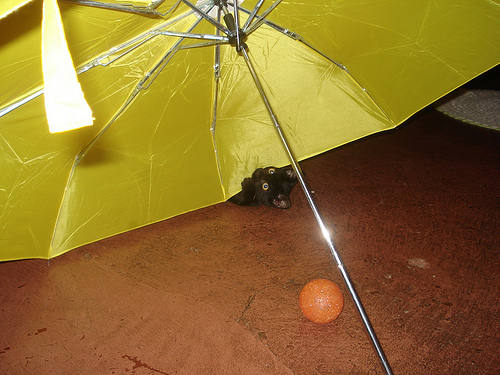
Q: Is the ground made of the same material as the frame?
A: No, the ground is made of cement and the frame is made of metal.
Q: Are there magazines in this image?
A: No, there are no magazines.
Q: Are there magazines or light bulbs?
A: No, there are no magazines or light bulbs.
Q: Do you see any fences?
A: No, there are no fences.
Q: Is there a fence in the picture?
A: No, there are no fences.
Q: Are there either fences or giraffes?
A: No, there are no fences or giraffes.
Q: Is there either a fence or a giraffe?
A: No, there are no fences or giraffes.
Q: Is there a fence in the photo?
A: No, there are no fences.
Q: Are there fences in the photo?
A: No, there are no fences.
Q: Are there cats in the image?
A: Yes, there is a cat.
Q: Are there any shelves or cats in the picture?
A: Yes, there is a cat.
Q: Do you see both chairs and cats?
A: No, there is a cat but no chairs.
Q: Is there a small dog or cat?
A: Yes, there is a small cat.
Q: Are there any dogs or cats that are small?
A: Yes, the cat is small.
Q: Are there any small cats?
A: Yes, there is a small cat.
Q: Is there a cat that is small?
A: Yes, there is a cat that is small.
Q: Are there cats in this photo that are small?
A: Yes, there is a cat that is small.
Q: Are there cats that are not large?
A: Yes, there is a small cat.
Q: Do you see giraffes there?
A: No, there are no giraffes.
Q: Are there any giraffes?
A: No, there are no giraffes.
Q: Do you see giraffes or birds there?
A: No, there are no giraffes or birds.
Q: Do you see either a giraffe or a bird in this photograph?
A: No, there are no giraffes or birds.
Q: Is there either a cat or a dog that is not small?
A: No, there is a cat but it is small.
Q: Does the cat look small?
A: Yes, the cat is small.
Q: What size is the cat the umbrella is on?
A: The cat is small.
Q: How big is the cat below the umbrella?
A: The cat is small.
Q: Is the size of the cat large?
A: No, the cat is small.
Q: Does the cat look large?
A: No, the cat is small.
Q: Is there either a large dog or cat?
A: No, there is a cat but it is small.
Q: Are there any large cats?
A: No, there is a cat but it is small.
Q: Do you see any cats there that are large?
A: No, there is a cat but it is small.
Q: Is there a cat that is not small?
A: No, there is a cat but it is small.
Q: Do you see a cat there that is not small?
A: No, there is a cat but it is small.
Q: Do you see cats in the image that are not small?
A: No, there is a cat but it is small.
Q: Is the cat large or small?
A: The cat is small.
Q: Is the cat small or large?
A: The cat is small.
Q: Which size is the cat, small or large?
A: The cat is small.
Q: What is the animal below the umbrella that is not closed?
A: The animal is a cat.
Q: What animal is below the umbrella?
A: The animal is a cat.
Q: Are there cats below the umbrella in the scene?
A: Yes, there is a cat below the umbrella.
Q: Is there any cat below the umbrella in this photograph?
A: Yes, there is a cat below the umbrella.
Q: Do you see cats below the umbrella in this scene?
A: Yes, there is a cat below the umbrella.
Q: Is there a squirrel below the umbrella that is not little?
A: No, there is a cat below the umbrella.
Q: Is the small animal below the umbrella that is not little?
A: Yes, the cat is below the umbrella.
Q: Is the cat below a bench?
A: No, the cat is below the umbrella.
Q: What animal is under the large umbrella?
A: The cat is under the umbrella.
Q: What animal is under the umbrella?
A: The cat is under the umbrella.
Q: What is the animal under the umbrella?
A: The animal is a cat.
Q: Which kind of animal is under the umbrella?
A: The animal is a cat.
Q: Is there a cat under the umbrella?
A: Yes, there is a cat under the umbrella.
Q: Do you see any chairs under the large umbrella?
A: No, there is a cat under the umbrella.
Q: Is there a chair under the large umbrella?
A: No, there is a cat under the umbrella.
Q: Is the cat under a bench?
A: No, the cat is under the umbrella.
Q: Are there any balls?
A: Yes, there is a ball.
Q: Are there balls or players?
A: Yes, there is a ball.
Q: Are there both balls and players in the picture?
A: No, there is a ball but no players.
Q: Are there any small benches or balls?
A: Yes, there is a small ball.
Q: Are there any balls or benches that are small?
A: Yes, the ball is small.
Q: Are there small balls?
A: Yes, there is a small ball.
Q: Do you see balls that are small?
A: Yes, there is a ball that is small.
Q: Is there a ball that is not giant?
A: Yes, there is a small ball.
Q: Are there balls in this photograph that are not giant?
A: Yes, there is a small ball.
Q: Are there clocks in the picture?
A: No, there are no clocks.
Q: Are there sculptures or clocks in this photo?
A: No, there are no clocks or sculptures.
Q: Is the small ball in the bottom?
A: Yes, the ball is in the bottom of the image.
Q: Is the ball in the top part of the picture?
A: No, the ball is in the bottom of the image.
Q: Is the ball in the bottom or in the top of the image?
A: The ball is in the bottom of the image.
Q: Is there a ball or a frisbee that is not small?
A: No, there is a ball but it is small.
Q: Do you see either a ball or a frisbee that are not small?
A: No, there is a ball but it is small.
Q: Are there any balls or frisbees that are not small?
A: No, there is a ball but it is small.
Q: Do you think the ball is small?
A: Yes, the ball is small.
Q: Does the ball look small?
A: Yes, the ball is small.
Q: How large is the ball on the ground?
A: The ball is small.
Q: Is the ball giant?
A: No, the ball is small.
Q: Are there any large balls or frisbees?
A: No, there is a ball but it is small.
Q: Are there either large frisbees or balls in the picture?
A: No, there is a ball but it is small.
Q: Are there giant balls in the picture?
A: No, there is a ball but it is small.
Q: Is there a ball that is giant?
A: No, there is a ball but it is small.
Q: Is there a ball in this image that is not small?
A: No, there is a ball but it is small.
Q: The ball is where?
A: The ball is on the ground.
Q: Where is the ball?
A: The ball is on the ground.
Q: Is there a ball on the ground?
A: Yes, there is a ball on the ground.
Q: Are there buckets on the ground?
A: No, there is a ball on the ground.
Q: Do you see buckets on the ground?
A: No, there is a ball on the ground.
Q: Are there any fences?
A: No, there are no fences.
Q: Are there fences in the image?
A: No, there are no fences.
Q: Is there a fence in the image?
A: No, there are no fences.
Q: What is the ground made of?
A: The ground is made of concrete.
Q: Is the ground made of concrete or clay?
A: The ground is made of concrete.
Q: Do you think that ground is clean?
A: Yes, the ground is clean.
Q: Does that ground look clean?
A: Yes, the ground is clean.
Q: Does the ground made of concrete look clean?
A: Yes, the ground is clean.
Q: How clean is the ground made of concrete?
A: The ground is clean.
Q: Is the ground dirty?
A: No, the ground is clean.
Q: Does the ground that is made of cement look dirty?
A: No, the ground is clean.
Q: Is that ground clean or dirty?
A: The ground is clean.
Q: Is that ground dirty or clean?
A: The ground is clean.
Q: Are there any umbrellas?
A: Yes, there is an umbrella.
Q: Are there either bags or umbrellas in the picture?
A: Yes, there is an umbrella.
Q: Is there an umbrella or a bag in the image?
A: Yes, there is an umbrella.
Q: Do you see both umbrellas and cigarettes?
A: No, there is an umbrella but no cigarettes.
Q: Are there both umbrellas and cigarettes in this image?
A: No, there is an umbrella but no cigarettes.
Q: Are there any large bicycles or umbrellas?
A: Yes, there is a large umbrella.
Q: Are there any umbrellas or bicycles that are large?
A: Yes, the umbrella is large.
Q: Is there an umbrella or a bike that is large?
A: Yes, the umbrella is large.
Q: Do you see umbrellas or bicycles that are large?
A: Yes, the umbrella is large.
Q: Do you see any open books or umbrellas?
A: Yes, there is an open umbrella.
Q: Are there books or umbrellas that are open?
A: Yes, the umbrella is open.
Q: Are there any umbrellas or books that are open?
A: Yes, the umbrella is open.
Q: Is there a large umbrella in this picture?
A: Yes, there is a large umbrella.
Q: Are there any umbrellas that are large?
A: Yes, there is an umbrella that is large.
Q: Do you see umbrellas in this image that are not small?
A: Yes, there is a large umbrella.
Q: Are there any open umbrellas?
A: Yes, there is an open umbrella.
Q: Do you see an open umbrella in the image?
A: Yes, there is an open umbrella.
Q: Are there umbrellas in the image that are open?
A: Yes, there is an umbrella that is open.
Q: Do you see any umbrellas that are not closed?
A: Yes, there is a open umbrella.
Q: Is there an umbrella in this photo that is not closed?
A: Yes, there is a open umbrella.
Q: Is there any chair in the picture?
A: No, there are no chairs.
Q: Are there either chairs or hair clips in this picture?
A: No, there are no chairs or hair clips.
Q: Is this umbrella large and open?
A: Yes, the umbrella is large and open.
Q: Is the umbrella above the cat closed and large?
A: No, the umbrella is large but open.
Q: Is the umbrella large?
A: Yes, the umbrella is large.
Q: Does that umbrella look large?
A: Yes, the umbrella is large.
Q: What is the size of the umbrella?
A: The umbrella is large.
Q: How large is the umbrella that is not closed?
A: The umbrella is large.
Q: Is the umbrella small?
A: No, the umbrella is large.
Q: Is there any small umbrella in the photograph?
A: No, there is an umbrella but it is large.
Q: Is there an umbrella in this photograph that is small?
A: No, there is an umbrella but it is large.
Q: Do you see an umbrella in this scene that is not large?
A: No, there is an umbrella but it is large.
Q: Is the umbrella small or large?
A: The umbrella is large.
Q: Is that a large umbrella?
A: Yes, that is a large umbrella.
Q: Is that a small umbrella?
A: No, that is a large umbrella.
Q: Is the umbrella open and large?
A: Yes, the umbrella is open and large.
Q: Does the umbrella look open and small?
A: No, the umbrella is open but large.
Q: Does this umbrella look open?
A: Yes, the umbrella is open.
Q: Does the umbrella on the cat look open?
A: Yes, the umbrella is open.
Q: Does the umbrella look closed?
A: No, the umbrella is open.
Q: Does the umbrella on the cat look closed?
A: No, the umbrella is open.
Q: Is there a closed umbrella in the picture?
A: No, there is an umbrella but it is open.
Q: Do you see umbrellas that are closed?
A: No, there is an umbrella but it is open.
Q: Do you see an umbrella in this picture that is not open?
A: No, there is an umbrella but it is open.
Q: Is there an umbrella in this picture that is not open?
A: No, there is an umbrella but it is open.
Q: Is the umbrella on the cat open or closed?
A: The umbrella is open.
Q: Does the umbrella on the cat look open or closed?
A: The umbrella is open.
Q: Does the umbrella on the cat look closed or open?
A: The umbrella is open.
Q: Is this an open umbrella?
A: Yes, this is an open umbrella.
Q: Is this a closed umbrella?
A: No, this is an open umbrella.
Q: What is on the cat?
A: The umbrella is on the cat.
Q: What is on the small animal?
A: The umbrella is on the cat.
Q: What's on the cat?
A: The umbrella is on the cat.